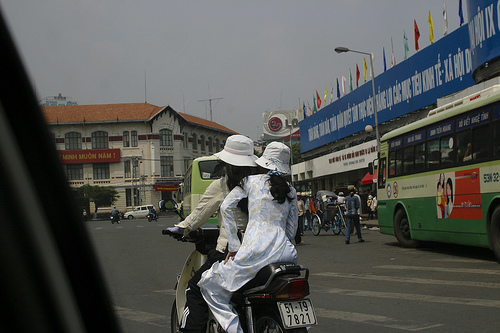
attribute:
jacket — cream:
[175, 172, 251, 325]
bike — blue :
[322, 160, 384, 258]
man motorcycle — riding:
[107, 204, 122, 226]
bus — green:
[375, 103, 497, 262]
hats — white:
[221, 124, 293, 182]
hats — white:
[221, 115, 299, 172]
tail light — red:
[288, 275, 310, 296]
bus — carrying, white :
[369, 78, 499, 263]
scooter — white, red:
[108, 214, 118, 220]